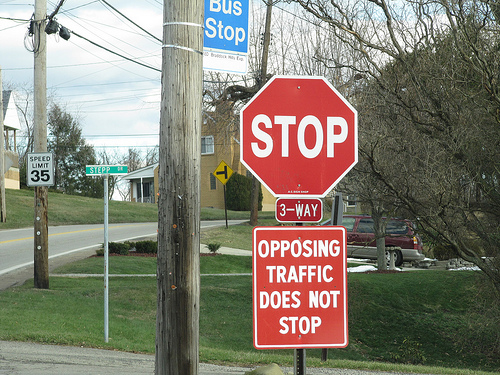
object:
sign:
[240, 75, 359, 199]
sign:
[274, 197, 323, 222]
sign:
[252, 225, 348, 350]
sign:
[203, 0, 250, 75]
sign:
[26, 153, 55, 187]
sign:
[86, 165, 129, 176]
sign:
[213, 160, 234, 185]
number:
[31, 169, 50, 182]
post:
[103, 177, 109, 343]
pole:
[152, 0, 205, 375]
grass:
[38, 305, 73, 328]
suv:
[315, 214, 425, 267]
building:
[4, 90, 20, 190]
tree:
[264, 0, 500, 301]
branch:
[368, 0, 404, 56]